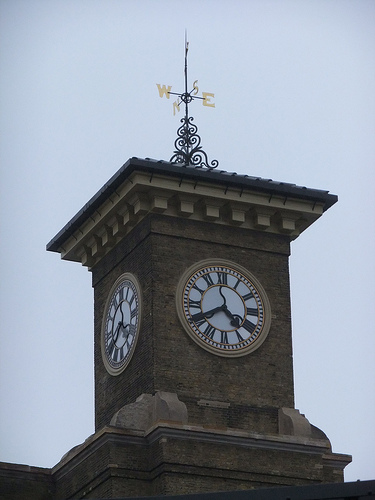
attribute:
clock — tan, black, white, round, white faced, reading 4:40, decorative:
[177, 256, 275, 359]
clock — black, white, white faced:
[101, 273, 142, 376]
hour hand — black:
[221, 306, 240, 327]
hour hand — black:
[117, 321, 131, 333]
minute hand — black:
[189, 307, 223, 322]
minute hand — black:
[107, 322, 122, 354]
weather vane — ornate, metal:
[157, 30, 220, 168]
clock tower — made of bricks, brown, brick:
[45, 156, 339, 448]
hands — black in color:
[189, 306, 240, 327]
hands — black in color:
[107, 323, 127, 352]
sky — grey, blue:
[2, 0, 373, 482]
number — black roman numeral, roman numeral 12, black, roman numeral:
[216, 271, 227, 288]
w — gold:
[157, 82, 172, 99]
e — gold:
[201, 91, 213, 109]